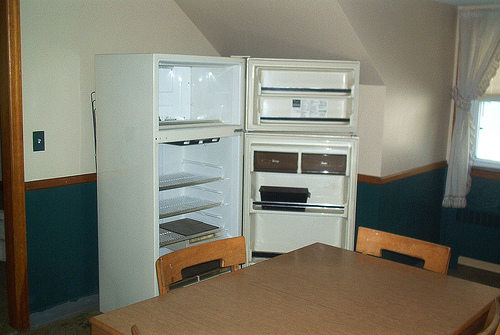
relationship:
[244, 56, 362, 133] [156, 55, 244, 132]
door open on freezer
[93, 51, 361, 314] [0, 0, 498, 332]
fridge in kitchen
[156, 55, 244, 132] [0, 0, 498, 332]
freezer in kitchen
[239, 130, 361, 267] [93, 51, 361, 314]
door open on fridge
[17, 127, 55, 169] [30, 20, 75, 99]
switch on wall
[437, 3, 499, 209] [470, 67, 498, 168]
curtain in window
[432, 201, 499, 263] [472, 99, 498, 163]
heating vents under kitchen window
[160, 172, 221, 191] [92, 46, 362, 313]
shelf in refrigerator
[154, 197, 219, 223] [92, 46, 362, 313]
shelf in refrigerator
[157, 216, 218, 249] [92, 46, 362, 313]
shelf in refrigerator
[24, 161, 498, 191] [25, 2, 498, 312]
rail along walls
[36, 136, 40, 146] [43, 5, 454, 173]
light switch on wall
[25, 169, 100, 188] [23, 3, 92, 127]
wood grain on wall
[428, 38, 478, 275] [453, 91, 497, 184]
curtain over window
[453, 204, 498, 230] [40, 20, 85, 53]
vent on wall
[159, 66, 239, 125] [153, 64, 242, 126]
inside of freezer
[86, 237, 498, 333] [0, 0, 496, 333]
table in kitchen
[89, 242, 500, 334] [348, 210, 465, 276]
table with chair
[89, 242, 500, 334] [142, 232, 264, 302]
table with chair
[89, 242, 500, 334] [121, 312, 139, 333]
table with chair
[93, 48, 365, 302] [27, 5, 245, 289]
fridge on wall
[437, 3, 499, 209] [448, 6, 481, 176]
curtain on window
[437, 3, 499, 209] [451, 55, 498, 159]
curtain on kitchen window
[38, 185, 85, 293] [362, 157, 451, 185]
wainscoting with border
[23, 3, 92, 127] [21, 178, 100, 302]
wall above wainscoting